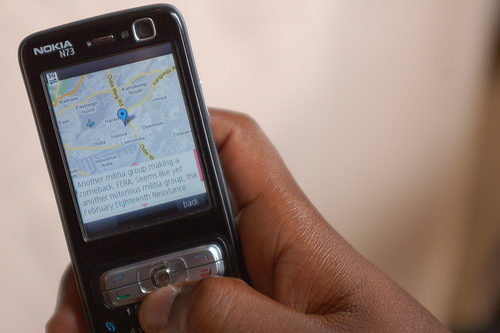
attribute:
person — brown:
[27, 103, 471, 330]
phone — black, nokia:
[11, 1, 254, 330]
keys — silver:
[96, 243, 233, 312]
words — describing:
[71, 152, 201, 217]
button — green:
[108, 286, 136, 305]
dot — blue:
[115, 104, 130, 126]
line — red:
[187, 147, 206, 186]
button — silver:
[144, 258, 181, 290]